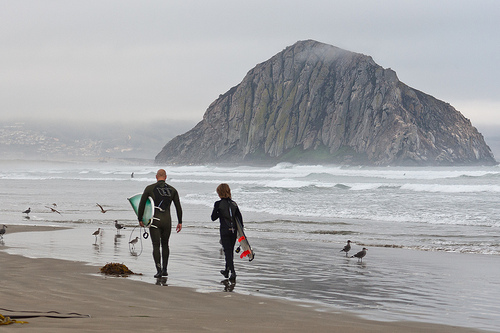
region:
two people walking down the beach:
[127, 159, 273, 307]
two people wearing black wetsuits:
[143, 165, 268, 294]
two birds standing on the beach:
[336, 236, 373, 263]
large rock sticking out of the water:
[125, 28, 490, 183]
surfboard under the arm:
[124, 191, 166, 230]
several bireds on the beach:
[8, 188, 162, 265]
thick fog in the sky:
[3, 1, 498, 151]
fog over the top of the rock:
[293, 40, 354, 72]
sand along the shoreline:
[1, 252, 474, 329]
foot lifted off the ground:
[216, 266, 229, 279]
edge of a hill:
[346, 51, 386, 106]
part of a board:
[236, 224, 268, 256]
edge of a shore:
[295, 290, 320, 321]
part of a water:
[401, 205, 438, 260]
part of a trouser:
[226, 231, 243, 269]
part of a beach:
[312, 247, 344, 302]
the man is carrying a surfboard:
[128, 168, 181, 274]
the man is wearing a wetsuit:
[138, 181, 182, 266]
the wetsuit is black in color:
[143, 184, 183, 279]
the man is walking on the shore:
[133, 169, 188, 284]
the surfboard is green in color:
[126, 190, 157, 225]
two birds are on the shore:
[340, 237, 368, 262]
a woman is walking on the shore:
[211, 186, 248, 289]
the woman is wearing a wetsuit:
[211, 201, 241, 278]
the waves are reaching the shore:
[118, 167, 493, 211]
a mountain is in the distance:
[161, 35, 482, 175]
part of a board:
[238, 233, 255, 265]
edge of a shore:
[386, 213, 415, 265]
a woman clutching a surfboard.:
[198, 177, 257, 302]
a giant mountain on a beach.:
[156, 32, 496, 165]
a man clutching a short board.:
[121, 157, 191, 294]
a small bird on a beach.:
[341, 235, 378, 272]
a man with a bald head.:
[147, 164, 171, 188]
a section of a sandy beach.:
[2, 227, 437, 331]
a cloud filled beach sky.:
[0, 0, 499, 124]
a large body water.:
[1, 121, 498, 332]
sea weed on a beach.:
[85, 257, 155, 282]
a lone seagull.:
[351, 239, 372, 266]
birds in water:
[332, 223, 392, 302]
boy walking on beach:
[208, 179, 269, 324]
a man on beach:
[132, 168, 193, 277]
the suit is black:
[142, 181, 207, 266]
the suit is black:
[206, 200, 257, 287]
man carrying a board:
[124, 176, 184, 236]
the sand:
[116, 295, 176, 325]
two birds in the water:
[340, 238, 381, 265]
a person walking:
[210, 183, 250, 284]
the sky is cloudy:
[56, 44, 130, 88]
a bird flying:
[37, 195, 69, 218]